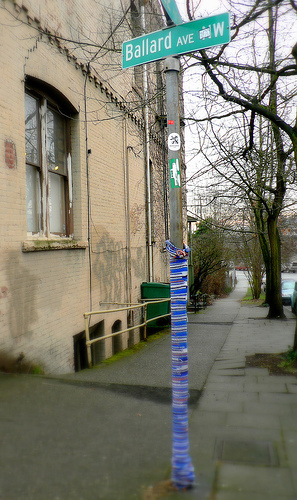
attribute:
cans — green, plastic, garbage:
[138, 280, 171, 330]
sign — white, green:
[120, 11, 230, 68]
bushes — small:
[189, 215, 230, 296]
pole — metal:
[161, 55, 199, 489]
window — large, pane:
[22, 84, 74, 239]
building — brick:
[0, 0, 188, 377]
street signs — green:
[90, 1, 241, 74]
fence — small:
[81, 297, 171, 368]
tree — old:
[232, 202, 263, 300]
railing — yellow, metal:
[80, 293, 180, 370]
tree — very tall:
[179, 0, 294, 320]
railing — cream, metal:
[74, 296, 171, 366]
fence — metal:
[83, 291, 180, 367]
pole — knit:
[162, 239, 192, 487]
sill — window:
[23, 230, 89, 249]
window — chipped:
[15, 72, 90, 254]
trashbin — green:
[138, 279, 177, 337]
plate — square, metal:
[212, 434, 281, 465]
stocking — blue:
[170, 241, 194, 489]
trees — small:
[249, 82, 286, 319]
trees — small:
[235, 219, 262, 298]